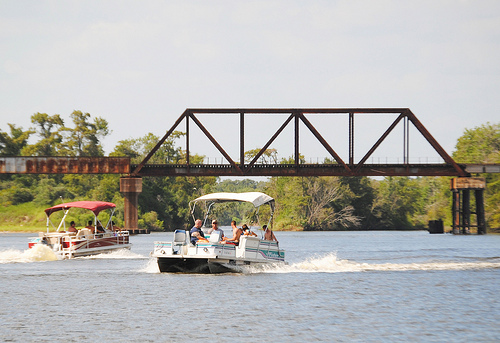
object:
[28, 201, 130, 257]
pontoon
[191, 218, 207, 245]
men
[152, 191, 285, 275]
boat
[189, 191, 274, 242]
canopy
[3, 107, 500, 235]
bridge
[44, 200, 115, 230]
canopy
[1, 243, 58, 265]
wake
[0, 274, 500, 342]
water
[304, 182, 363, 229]
tree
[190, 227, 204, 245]
shirt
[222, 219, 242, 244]
man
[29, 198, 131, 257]
boating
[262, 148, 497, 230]
island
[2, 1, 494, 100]
sky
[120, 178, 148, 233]
pillar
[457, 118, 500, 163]
foliage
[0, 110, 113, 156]
trees